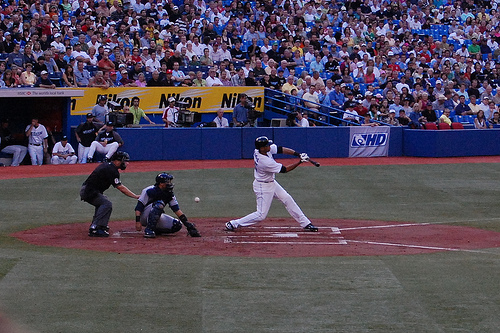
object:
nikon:
[221, 94, 262, 109]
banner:
[55, 87, 266, 116]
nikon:
[159, 93, 202, 113]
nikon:
[97, 94, 140, 115]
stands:
[1, 0, 499, 129]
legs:
[3, 144, 21, 167]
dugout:
[3, 97, 74, 160]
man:
[0, 119, 26, 167]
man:
[127, 96, 156, 127]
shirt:
[126, 107, 145, 126]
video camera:
[176, 100, 202, 126]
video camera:
[106, 101, 134, 130]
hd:
[367, 132, 388, 148]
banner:
[349, 125, 391, 157]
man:
[467, 37, 480, 55]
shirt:
[466, 45, 480, 52]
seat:
[454, 122, 465, 129]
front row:
[411, 113, 499, 130]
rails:
[262, 89, 393, 129]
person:
[175, 12, 187, 35]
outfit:
[173, 19, 189, 33]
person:
[162, 70, 174, 88]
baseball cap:
[165, 68, 172, 75]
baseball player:
[224, 137, 320, 232]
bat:
[309, 160, 320, 170]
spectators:
[2, 0, 499, 129]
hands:
[299, 154, 309, 163]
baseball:
[193, 196, 200, 202]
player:
[24, 117, 49, 165]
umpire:
[78, 151, 142, 237]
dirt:
[10, 216, 499, 256]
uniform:
[231, 144, 311, 230]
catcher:
[135, 173, 201, 239]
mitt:
[186, 224, 199, 238]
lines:
[226, 220, 494, 258]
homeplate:
[270, 231, 297, 239]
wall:
[78, 126, 500, 160]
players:
[86, 121, 122, 162]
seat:
[412, 29, 427, 36]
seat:
[425, 28, 438, 40]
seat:
[443, 28, 449, 38]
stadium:
[0, 1, 499, 281]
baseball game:
[0, 155, 499, 332]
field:
[0, 157, 497, 333]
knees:
[98, 201, 113, 213]